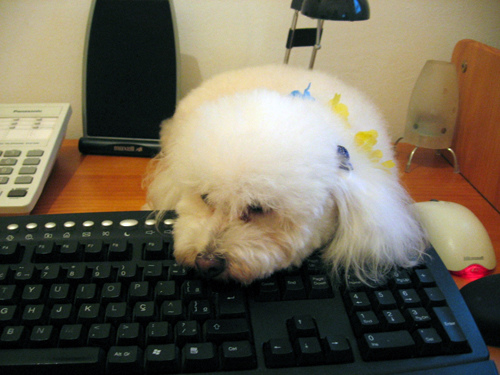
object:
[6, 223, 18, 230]
button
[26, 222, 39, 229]
button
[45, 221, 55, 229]
button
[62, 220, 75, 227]
button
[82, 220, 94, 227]
button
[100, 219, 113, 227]
button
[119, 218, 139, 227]
button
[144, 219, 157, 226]
button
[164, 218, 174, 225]
button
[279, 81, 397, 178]
flowers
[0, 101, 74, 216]
telephone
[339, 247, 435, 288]
number pad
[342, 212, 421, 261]
fluffy fur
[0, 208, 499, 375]
keyboard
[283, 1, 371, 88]
lamp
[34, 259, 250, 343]
keys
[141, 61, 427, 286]
dog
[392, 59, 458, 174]
table lamp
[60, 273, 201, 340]
buttons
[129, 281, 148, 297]
key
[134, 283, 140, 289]
letter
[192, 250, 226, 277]
nose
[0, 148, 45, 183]
grey buttons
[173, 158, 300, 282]
face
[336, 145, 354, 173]
bow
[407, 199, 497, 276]
mouse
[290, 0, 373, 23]
hood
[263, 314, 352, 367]
keys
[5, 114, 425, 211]
desk top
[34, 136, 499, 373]
brown table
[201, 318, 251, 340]
key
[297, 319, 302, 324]
arrow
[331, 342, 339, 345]
arrow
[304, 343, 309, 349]
arrow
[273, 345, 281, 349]
arrow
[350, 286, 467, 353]
buttons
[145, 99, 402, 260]
dog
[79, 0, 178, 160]
speaker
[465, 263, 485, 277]
light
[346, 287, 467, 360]
keys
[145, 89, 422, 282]
head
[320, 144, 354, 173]
collar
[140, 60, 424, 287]
fur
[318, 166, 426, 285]
ear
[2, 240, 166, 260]
buttons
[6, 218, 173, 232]
function keys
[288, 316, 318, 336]
up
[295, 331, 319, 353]
down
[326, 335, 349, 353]
right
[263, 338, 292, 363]
left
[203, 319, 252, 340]
shift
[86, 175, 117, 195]
part